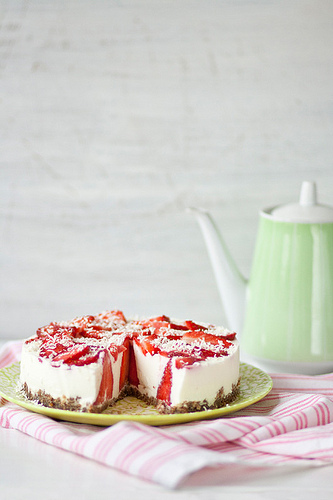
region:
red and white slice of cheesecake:
[22, 314, 121, 395]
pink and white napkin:
[138, 439, 175, 471]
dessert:
[135, 314, 222, 394]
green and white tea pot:
[186, 175, 330, 292]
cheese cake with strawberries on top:
[21, 309, 238, 412]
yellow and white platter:
[1, 363, 272, 426]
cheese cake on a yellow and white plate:
[2, 309, 272, 426]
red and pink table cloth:
[0, 374, 332, 490]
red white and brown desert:
[19, 310, 236, 411]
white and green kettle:
[187, 180, 331, 373]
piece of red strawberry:
[88, 352, 114, 404]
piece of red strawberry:
[158, 354, 173, 403]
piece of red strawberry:
[186, 328, 233, 346]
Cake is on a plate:
[17, 286, 278, 429]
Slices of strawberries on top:
[24, 299, 239, 372]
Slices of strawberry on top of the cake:
[18, 288, 244, 372]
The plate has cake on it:
[5, 352, 271, 425]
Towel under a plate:
[168, 408, 295, 481]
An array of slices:
[33, 304, 235, 368]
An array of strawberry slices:
[41, 311, 224, 365]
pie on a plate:
[223, 347, 244, 389]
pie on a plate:
[162, 316, 186, 336]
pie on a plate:
[126, 314, 150, 333]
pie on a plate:
[88, 309, 117, 337]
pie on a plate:
[39, 328, 61, 346]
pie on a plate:
[55, 348, 81, 372]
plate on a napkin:
[126, 408, 162, 426]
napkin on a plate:
[170, 437, 243, 493]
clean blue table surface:
[28, 473, 72, 483]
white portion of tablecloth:
[162, 464, 184, 476]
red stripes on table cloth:
[278, 415, 326, 435]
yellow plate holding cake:
[108, 406, 184, 430]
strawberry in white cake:
[149, 368, 181, 401]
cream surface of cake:
[178, 374, 215, 392]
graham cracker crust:
[150, 401, 227, 418]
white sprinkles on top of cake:
[106, 317, 223, 360]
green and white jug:
[199, 180, 326, 336]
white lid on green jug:
[270, 178, 325, 224]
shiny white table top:
[1, 424, 332, 499]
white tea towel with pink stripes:
[0, 334, 332, 489]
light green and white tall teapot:
[185, 180, 332, 375]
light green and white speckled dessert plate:
[0, 356, 274, 426]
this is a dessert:
[15, 145, 262, 465]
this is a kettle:
[234, 202, 329, 358]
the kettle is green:
[217, 176, 317, 307]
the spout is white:
[176, 192, 247, 273]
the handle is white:
[285, 167, 330, 213]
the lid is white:
[271, 184, 330, 232]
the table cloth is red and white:
[102, 424, 215, 470]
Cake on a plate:
[31, 296, 245, 419]